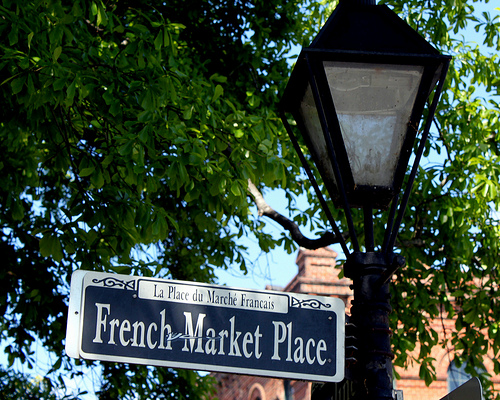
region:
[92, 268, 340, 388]
the signboard is white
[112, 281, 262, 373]
the signboard is white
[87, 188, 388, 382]
the signboard is white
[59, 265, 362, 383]
the blue and white street sign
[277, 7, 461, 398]
the black street light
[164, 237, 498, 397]
the brick building in the back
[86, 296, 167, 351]
the word French on the sign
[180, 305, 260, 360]
the word Market on the sign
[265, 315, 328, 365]
the word Place on the sign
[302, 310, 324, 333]
the blue on the sign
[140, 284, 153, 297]
the white on the sign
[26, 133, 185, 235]
the leaves on the tree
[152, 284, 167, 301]
the word La on the sign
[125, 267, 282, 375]
a sign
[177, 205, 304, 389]
a sign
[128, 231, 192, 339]
a sign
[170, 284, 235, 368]
a sign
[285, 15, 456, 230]
The light is off.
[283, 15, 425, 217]
The light is black.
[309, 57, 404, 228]
The glass is frosted.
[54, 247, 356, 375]
The sign is black.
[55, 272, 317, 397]
The lettering is white.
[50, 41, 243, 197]
The tree is leafy.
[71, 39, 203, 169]
The tree is green.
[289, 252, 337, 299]
The building is brick.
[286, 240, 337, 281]
The building is red.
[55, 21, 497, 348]
The sun is shining.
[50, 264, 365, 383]
sign near an outdoor light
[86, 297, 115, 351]
white letter on a sign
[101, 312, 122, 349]
white letter on a sign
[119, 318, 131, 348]
white letter on a sign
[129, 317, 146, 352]
white letter on a sign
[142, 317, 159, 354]
white letter on a sign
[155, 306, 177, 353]
white letter on a sign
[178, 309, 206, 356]
white letter on a sign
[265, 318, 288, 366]
white letter on a sign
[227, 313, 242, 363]
white letter on a sign